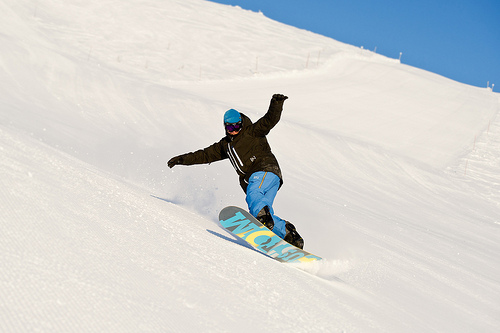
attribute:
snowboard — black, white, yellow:
[216, 206, 329, 273]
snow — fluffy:
[0, 0, 497, 331]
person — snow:
[146, 75, 338, 265]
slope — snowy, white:
[4, 0, 498, 329]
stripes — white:
[224, 138, 246, 178]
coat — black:
[174, 97, 283, 192]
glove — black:
[264, 90, 288, 108]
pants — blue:
[254, 175, 295, 222]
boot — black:
[285, 223, 310, 248]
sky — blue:
[230, 2, 499, 86]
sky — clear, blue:
[347, 36, 481, 81]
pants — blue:
[238, 164, 305, 260]